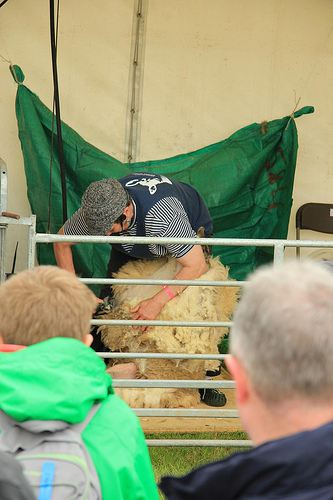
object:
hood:
[0, 337, 113, 424]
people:
[0, 257, 333, 500]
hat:
[82, 179, 129, 236]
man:
[156, 257, 333, 500]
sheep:
[93, 254, 241, 408]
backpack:
[0, 403, 100, 500]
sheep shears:
[97, 296, 118, 311]